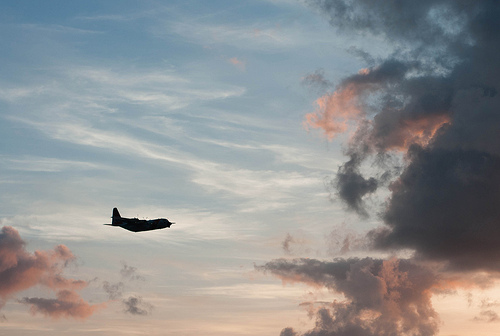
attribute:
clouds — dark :
[360, 100, 445, 225]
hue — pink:
[431, 281, 483, 332]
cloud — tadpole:
[315, 46, 441, 205]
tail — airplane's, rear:
[104, 209, 118, 227]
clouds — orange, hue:
[138, 70, 199, 110]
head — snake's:
[315, 128, 377, 205]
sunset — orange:
[336, 67, 432, 220]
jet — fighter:
[108, 193, 178, 234]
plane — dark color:
[103, 204, 177, 235]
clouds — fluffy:
[255, 77, 437, 333]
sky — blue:
[1, 1, 251, 100]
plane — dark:
[102, 205, 176, 241]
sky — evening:
[3, 1, 495, 332]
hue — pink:
[303, 83, 370, 139]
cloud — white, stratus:
[4, 62, 307, 214]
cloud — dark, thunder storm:
[368, 97, 496, 267]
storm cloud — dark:
[332, 7, 483, 285]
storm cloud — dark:
[252, 256, 444, 334]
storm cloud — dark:
[301, 58, 422, 143]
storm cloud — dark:
[304, 1, 448, 47]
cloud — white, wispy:
[60, 64, 194, 91]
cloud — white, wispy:
[2, 153, 124, 175]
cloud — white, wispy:
[5, 111, 331, 210]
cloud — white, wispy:
[141, 104, 300, 133]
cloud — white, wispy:
[2, 80, 60, 106]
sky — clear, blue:
[2, 2, 357, 291]